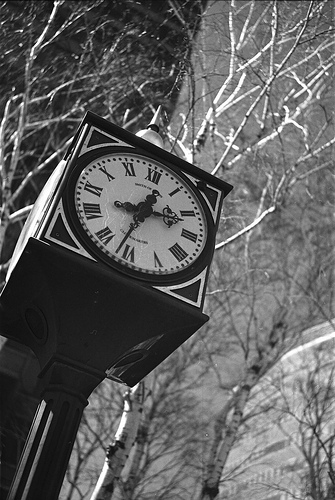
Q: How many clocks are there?
A: One.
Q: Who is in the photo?
A: No one.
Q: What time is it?
A: Daytime.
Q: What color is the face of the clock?
A: White.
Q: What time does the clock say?
A: 2:31.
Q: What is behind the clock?
A: Trees.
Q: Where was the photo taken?
A: On the street.